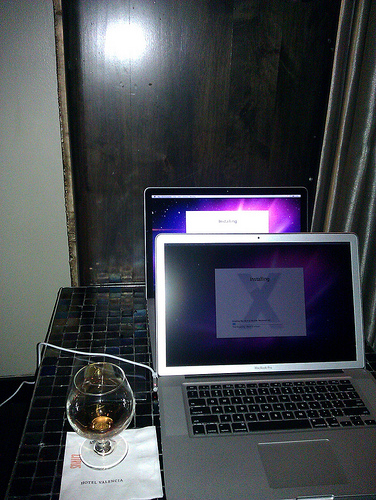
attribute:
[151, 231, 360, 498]
macbook — silver, open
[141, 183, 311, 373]
macbook — silver, open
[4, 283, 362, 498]
table — tiled, black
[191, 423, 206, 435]
key — black, white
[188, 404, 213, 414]
key — white, black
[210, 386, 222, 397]
key — black, white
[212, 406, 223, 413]
key — white, black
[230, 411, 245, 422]
key — black, white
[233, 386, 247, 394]
key — white, black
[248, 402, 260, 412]
key — black, white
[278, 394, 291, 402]
key — white, black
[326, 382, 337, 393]
key — black, white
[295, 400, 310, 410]
key — white, black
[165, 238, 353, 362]
screen — on, laptop 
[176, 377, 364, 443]
keyboard — black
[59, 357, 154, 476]
cup — glass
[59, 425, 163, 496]
napkin — white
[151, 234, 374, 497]
laptop — silver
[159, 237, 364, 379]
screen — laptop 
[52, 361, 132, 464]
glass — wine 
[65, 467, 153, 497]
paper — white 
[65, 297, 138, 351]
bricks — black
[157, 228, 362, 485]
laptop — grey , black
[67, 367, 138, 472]
glass — half full wine 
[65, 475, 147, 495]
napkin — Hotel 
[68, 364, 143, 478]
glass — wine 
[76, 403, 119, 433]
liquid —  light amber 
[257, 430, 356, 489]
touchpad — grey, square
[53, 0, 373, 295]
wood — dark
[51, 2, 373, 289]
door — black, dark, wooden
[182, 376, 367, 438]
keys — black, white